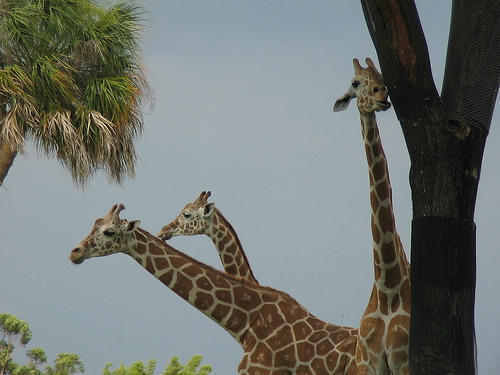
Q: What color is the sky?
A: Blue.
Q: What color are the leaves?
A: Green.